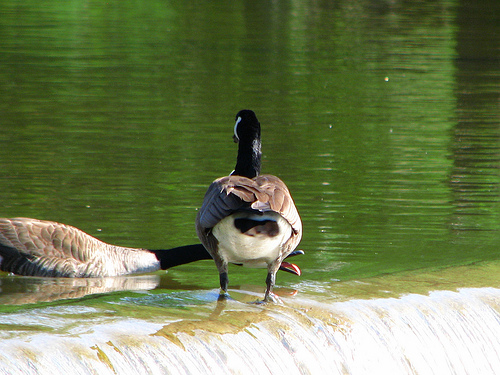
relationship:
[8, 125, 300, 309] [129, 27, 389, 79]
geese in water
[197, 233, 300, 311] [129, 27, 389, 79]
goose on top of water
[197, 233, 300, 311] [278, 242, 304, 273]
goose has mouth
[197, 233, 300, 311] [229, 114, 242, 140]
goose has mark